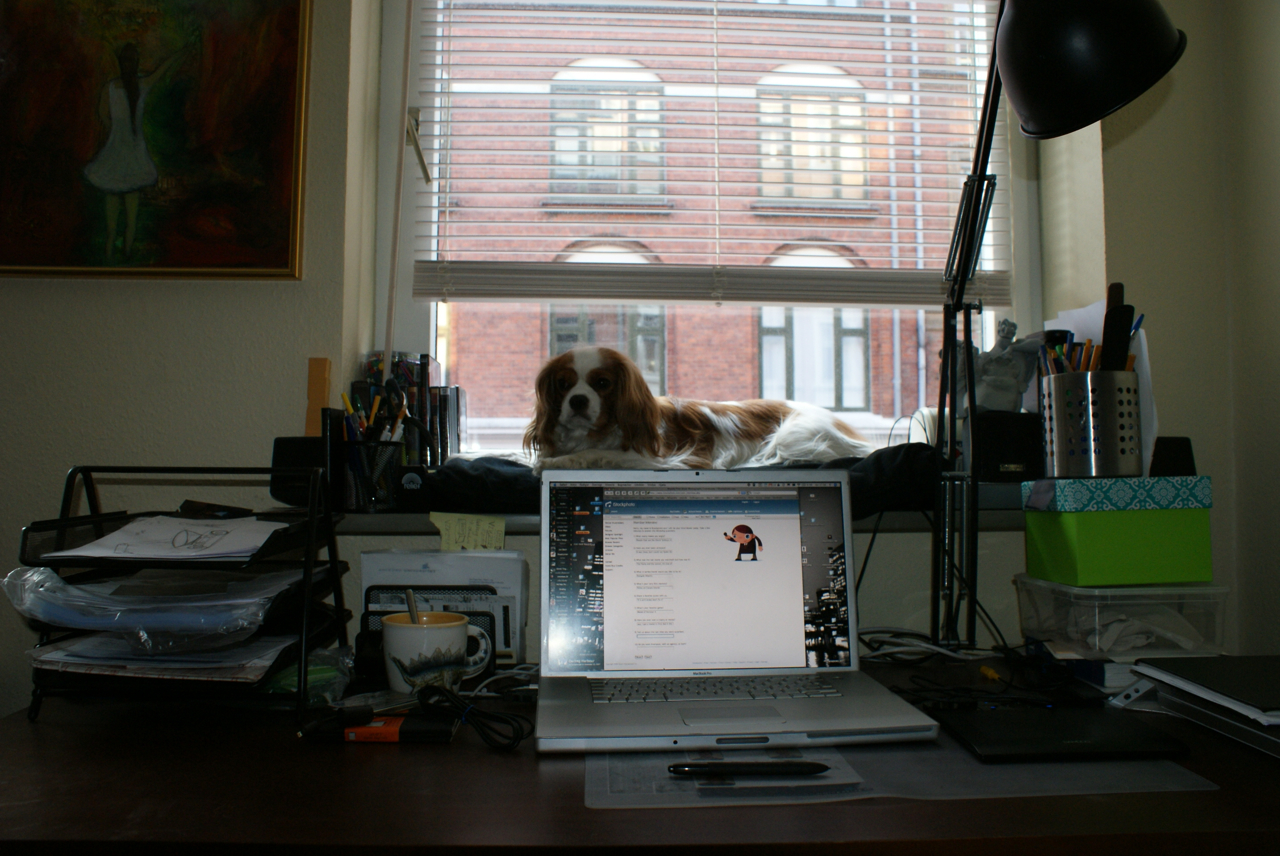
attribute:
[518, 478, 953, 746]
laptop — silver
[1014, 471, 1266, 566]
box — green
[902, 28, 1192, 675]
lamp — desk, black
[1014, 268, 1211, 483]
container — silver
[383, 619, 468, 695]
mug — white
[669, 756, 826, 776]
pen — black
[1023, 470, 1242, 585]
box — green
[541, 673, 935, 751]
keyboard — white 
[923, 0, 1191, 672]
lamp — black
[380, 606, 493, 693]
cup — white 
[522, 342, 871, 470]
dog — brown, white 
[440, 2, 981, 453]
building — red 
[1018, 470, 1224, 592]
box — blue, green 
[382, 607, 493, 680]
mug — orange 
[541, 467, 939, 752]
laptop — silver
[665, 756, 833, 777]
pen — black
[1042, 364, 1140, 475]
container — metal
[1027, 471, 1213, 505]
lid — decorative